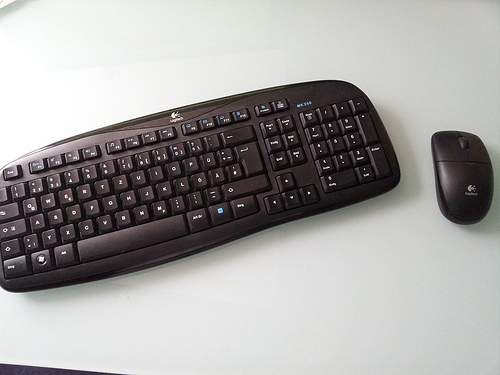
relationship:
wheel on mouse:
[455, 134, 471, 149] [427, 124, 497, 230]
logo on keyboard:
[164, 107, 186, 127] [0, 77, 404, 285]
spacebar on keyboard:
[75, 210, 192, 261] [0, 77, 404, 285]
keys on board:
[177, 141, 263, 219] [200, 75, 360, 106]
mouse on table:
[427, 124, 497, 230] [40, 8, 463, 65]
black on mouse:
[457, 168, 483, 181] [427, 124, 497, 230]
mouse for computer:
[427, 124, 497, 230] [0, 0, 56, 14]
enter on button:
[238, 142, 251, 153] [235, 133, 267, 180]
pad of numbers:
[297, 99, 394, 195] [317, 117, 359, 163]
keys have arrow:
[263, 171, 320, 213] [284, 190, 298, 201]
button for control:
[228, 191, 257, 219] [236, 202, 249, 209]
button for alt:
[187, 207, 210, 230] [192, 211, 205, 219]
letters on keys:
[74, 176, 197, 211] [177, 141, 263, 219]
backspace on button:
[224, 132, 234, 142] [217, 118, 254, 144]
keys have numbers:
[300, 101, 366, 171] [317, 117, 359, 163]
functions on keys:
[82, 148, 102, 161] [105, 121, 190, 154]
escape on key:
[8, 171, 13, 175] [1, 153, 30, 186]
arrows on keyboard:
[279, 177, 299, 200] [0, 77, 404, 285]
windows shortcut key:
[33, 256, 47, 264] [33, 249, 53, 271]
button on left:
[432, 123, 464, 167] [431, 120, 462, 220]